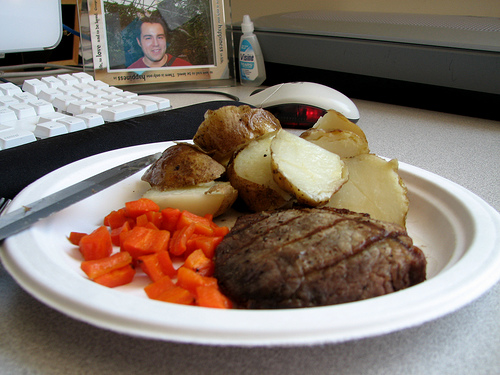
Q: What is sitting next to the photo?
A: Eye drops.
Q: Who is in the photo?
A: A man.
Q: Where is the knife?
A: On the plate.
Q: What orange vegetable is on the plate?
A: Carrots.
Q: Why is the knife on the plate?
A: To cut meat.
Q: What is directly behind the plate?
A: Computer mouse.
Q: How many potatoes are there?
A: Seven.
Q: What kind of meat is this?
A: Steak.